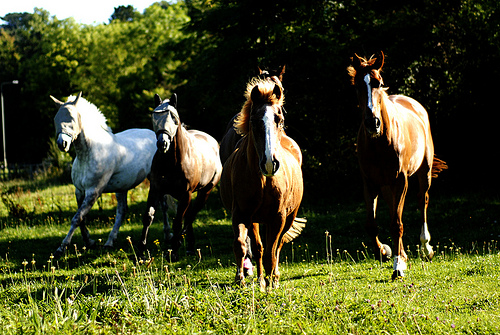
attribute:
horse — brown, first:
[220, 63, 304, 291]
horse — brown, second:
[345, 48, 447, 280]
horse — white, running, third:
[49, 92, 159, 251]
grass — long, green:
[2, 162, 500, 334]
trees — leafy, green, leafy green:
[1, 0, 499, 208]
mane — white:
[65, 94, 112, 135]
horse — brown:
[142, 89, 223, 257]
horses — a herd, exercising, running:
[48, 50, 450, 293]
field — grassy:
[0, 2, 499, 333]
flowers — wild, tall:
[22, 233, 499, 321]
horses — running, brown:
[153, 49, 448, 282]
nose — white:
[258, 155, 280, 179]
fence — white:
[2, 165, 37, 182]